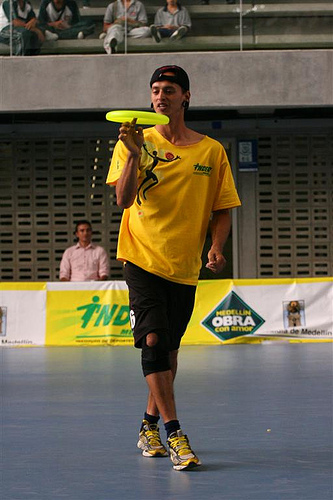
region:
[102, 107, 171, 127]
the frisbee is yellow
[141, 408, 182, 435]
the socks are black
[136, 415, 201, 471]
the sneakers are yellow and gray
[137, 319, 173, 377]
a black brace on the knee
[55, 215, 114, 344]
a man behind the sign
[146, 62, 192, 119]
the person is wearing a black hat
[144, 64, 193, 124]
the person's mouth is open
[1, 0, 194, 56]
people are sitting on the bleachers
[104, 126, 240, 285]
the shirt is yellow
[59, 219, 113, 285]
the man's shirt is pink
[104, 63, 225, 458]
person with a yellow frisbee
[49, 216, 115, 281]
man in a pink shirt watching event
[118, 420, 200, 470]
sneakers with yellow laces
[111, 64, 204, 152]
person wearing baseball hat backwards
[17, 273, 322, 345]
large banner covering fence along back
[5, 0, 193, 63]
spectators sitting in stands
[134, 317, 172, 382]
person wearing a black knee brace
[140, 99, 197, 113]
person with black gauge earrings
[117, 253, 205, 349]
person wearing black shorts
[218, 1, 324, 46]
cement seating area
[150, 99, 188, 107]
Large black earring gauges in the ears.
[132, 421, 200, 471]
Grey sneakers with yellow shoestrings.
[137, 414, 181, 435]
Dark colored above the ankle length socks.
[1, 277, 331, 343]
Yellow and white sponsor signs.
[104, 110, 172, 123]
A bright yellow frisbee.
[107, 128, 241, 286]
A yellow shirt with a design on it.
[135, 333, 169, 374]
A black knee brace.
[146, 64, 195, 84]
A black ball cap on backwards.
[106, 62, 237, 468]
A man balancing a frisbee on one of his fingers.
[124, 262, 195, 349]
Black sports shorts.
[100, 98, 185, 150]
man spinning yellow frisbee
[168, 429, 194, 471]
man wearing yellow and white shoes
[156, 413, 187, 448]
man wearing black socks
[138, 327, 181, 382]
man wearing black knee brace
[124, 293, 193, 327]
man wearing black shorts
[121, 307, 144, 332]
black shorts with white number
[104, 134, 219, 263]
man wearing yellow shirt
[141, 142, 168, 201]
yellow shirt with black logo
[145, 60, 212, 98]
man wearing black cap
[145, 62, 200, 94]
cap is turned backward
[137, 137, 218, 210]
Logos on tee-shirt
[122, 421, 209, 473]
Lots of yellow on the sneakers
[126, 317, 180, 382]
Brace on right knee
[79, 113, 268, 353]
Yellow shirt and black shorts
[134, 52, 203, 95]
Backwards cap on head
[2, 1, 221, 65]
Spectators in the stands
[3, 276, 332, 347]
Logos on the wall behind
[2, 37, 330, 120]
Building made of concrete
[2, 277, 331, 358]
Yellow and white checkered banner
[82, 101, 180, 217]
Spinning a frisbee on a finger